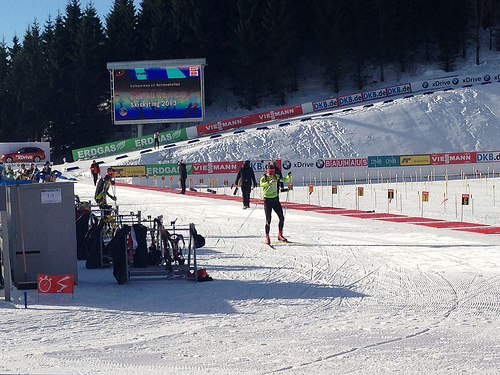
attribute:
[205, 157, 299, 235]
skiers — standing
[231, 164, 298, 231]
skier — wearing, here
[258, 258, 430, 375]
path — snow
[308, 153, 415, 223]
barrier — between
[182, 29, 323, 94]
trees — evergreen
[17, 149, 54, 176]
car — red, two door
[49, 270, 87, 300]
sign — red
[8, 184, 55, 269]
broom — long, brown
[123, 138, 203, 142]
advertisement — green, white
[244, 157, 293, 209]
person — wearing, walking, behind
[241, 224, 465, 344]
tracks — thin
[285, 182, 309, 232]
pole — thin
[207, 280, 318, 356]
ground — covered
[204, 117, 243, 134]
writing — white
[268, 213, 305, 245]
knee — bent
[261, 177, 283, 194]
shirt — green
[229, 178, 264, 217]
pants — black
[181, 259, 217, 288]
boot — red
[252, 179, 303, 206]
top — yellow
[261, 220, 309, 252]
boots — red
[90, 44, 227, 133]
billboard — framed, displayed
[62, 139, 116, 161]
banner — green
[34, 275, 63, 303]
stopwatch — white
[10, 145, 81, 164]
vehicle — displayed